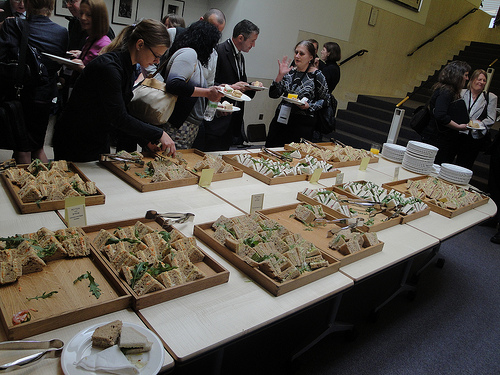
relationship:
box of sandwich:
[193, 212, 340, 297] [261, 258, 282, 279]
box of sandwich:
[193, 212, 340, 297] [212, 214, 234, 229]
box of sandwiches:
[1, 227, 131, 341] [1, 226, 91, 286]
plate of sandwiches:
[249, 80, 269, 92] [1, 226, 91, 286]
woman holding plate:
[265, 42, 331, 146] [164, 18, 252, 148]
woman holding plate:
[410, 60, 487, 142] [43, 1, 112, 68]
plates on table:
[382, 142, 406, 164] [4, 134, 488, 371]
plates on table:
[402, 139, 438, 175] [4, 134, 488, 371]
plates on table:
[438, 163, 473, 187] [4, 134, 488, 371]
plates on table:
[431, 164, 441, 176] [4, 134, 488, 371]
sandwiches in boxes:
[1, 226, 91, 286] [384, 174, 490, 217]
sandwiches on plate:
[221, 84, 251, 102] [217, 100, 240, 113]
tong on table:
[1, 339, 65, 373] [4, 134, 488, 371]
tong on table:
[146, 210, 196, 226] [4, 134, 488, 371]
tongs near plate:
[1, 339, 65, 373] [61, 319, 165, 374]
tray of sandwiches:
[82, 214, 229, 310] [133, 272, 166, 297]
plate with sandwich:
[61, 319, 165, 374] [120, 325, 152, 355]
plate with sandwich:
[61, 319, 165, 374] [92, 319, 122, 348]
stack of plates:
[382, 142, 406, 164] [402, 139, 438, 175]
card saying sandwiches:
[64, 197, 88, 229] [1, 220, 205, 296]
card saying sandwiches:
[250, 193, 265, 214] [293, 205, 379, 256]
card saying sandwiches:
[336, 171, 344, 187] [336, 180, 431, 221]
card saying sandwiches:
[197, 169, 217, 187] [193, 156, 233, 173]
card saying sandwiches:
[309, 166, 324, 183] [133, 272, 166, 297]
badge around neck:
[276, 103, 291, 125] [276, 65, 312, 128]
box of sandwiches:
[193, 212, 340, 297] [1, 226, 91, 286]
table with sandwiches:
[4, 134, 488, 371] [221, 151, 307, 189]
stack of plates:
[382, 142, 406, 164] [431, 164, 441, 176]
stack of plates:
[402, 139, 438, 175] [382, 139, 473, 186]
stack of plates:
[438, 163, 473, 187] [431, 164, 441, 176]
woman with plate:
[265, 42, 331, 146] [279, 91, 302, 108]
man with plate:
[220, 19, 268, 91] [249, 80, 269, 92]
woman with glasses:
[57, 19, 171, 154] [145, 42, 166, 63]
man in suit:
[220, 19, 268, 91] [213, 41, 247, 147]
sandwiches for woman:
[4, 134, 488, 371] [268, 40, 333, 145]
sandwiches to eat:
[133, 272, 166, 297] [232, 140, 372, 178]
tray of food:
[384, 174, 490, 217] [406, 176, 485, 211]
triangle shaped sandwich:
[18, 183, 42, 204] [149, 168, 169, 186]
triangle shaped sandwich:
[38, 236, 68, 261] [149, 168, 169, 186]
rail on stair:
[343, 48, 371, 69] [333, 117, 407, 146]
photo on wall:
[111, 1, 140, 27] [140, 2, 158, 18]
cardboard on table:
[250, 193, 265, 214] [4, 134, 488, 371]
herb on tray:
[27, 269, 105, 300] [1, 227, 131, 341]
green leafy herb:
[73, 270, 103, 301] [27, 269, 105, 300]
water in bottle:
[201, 103, 217, 119] [203, 86, 223, 121]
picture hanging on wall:
[160, 1, 185, 22] [55, 2, 267, 25]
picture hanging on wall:
[111, 1, 140, 27] [55, 2, 267, 25]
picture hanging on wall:
[54, 1, 79, 19] [55, 2, 267, 25]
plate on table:
[61, 319, 165, 374] [4, 134, 488, 371]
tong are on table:
[1, 339, 65, 373] [4, 134, 488, 371]